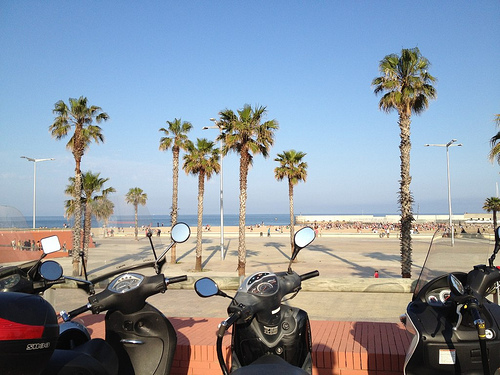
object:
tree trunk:
[396, 111, 415, 278]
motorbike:
[193, 226, 319, 375]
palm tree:
[48, 97, 110, 278]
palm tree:
[215, 104, 279, 278]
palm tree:
[274, 148, 308, 261]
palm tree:
[369, 43, 439, 278]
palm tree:
[158, 118, 194, 265]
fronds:
[216, 103, 279, 166]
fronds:
[371, 42, 438, 116]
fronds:
[48, 95, 109, 150]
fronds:
[125, 186, 148, 205]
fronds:
[63, 171, 117, 225]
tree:
[125, 187, 148, 241]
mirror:
[171, 223, 190, 243]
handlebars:
[60, 274, 187, 322]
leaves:
[158, 117, 194, 152]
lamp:
[17, 156, 60, 230]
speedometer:
[252, 279, 276, 294]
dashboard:
[108, 273, 144, 294]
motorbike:
[0, 222, 190, 375]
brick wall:
[52, 313, 417, 373]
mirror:
[294, 227, 315, 248]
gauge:
[248, 271, 279, 296]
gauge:
[108, 273, 144, 294]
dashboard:
[248, 273, 280, 297]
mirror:
[39, 234, 61, 254]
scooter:
[0, 234, 65, 306]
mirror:
[40, 261, 62, 280]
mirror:
[194, 277, 217, 298]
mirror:
[450, 270, 465, 296]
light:
[17, 156, 25, 159]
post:
[32, 161, 37, 231]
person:
[314, 223, 319, 238]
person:
[385, 226, 392, 238]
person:
[267, 228, 270, 237]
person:
[356, 224, 362, 233]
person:
[249, 224, 253, 232]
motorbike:
[396, 226, 500, 375]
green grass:
[108, 220, 136, 224]